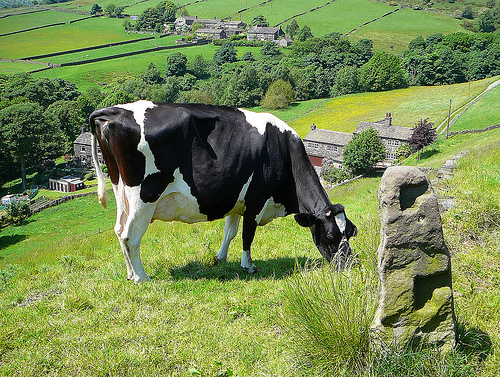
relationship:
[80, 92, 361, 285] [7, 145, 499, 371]
cow on hill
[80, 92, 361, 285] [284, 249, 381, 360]
cow eating grass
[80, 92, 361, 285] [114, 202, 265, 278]
cow has legs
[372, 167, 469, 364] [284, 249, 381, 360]
pillar on grass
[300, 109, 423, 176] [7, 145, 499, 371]
building at bottom of hill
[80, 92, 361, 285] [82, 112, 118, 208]
cow has tail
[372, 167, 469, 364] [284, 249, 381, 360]
pillar in grass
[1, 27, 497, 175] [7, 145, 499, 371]
trees at bottom of hill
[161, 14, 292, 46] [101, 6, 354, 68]
group in group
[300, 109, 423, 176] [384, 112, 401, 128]
building has chimney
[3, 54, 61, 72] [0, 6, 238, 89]
fence in field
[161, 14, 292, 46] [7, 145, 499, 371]
group at bottom of hill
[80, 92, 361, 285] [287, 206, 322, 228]
cow has ear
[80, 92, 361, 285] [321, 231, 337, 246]
cow has eye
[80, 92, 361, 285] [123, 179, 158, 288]
cow has leg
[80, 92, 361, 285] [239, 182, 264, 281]
cow has leg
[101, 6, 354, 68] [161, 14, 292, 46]
group of group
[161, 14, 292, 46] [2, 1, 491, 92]
group in distance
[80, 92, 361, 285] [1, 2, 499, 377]
cow in country side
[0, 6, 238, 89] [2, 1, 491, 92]
field in distance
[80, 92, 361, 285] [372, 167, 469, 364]
cow standing next to pillar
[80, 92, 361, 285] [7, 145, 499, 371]
cow standing on hill